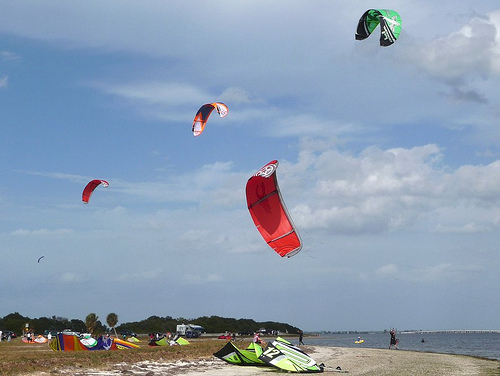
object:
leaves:
[156, 322, 159, 326]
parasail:
[245, 159, 304, 260]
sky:
[0, 0, 499, 332]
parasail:
[80, 178, 107, 205]